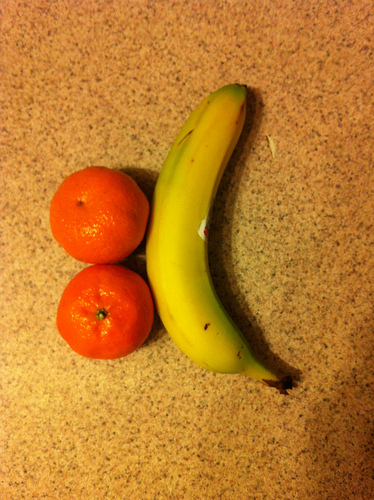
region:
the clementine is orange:
[51, 169, 154, 260]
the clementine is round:
[46, 162, 148, 262]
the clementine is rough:
[52, 266, 155, 360]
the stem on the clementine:
[89, 307, 112, 325]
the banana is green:
[143, 71, 302, 401]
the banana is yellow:
[140, 75, 297, 395]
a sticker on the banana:
[191, 217, 213, 242]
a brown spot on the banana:
[175, 126, 195, 145]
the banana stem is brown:
[245, 361, 290, 397]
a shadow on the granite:
[302, 309, 373, 497]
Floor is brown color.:
[34, 32, 152, 115]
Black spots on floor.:
[34, 380, 191, 459]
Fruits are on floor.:
[26, 177, 260, 389]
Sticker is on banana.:
[188, 205, 214, 252]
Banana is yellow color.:
[167, 178, 210, 310]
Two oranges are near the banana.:
[46, 174, 137, 362]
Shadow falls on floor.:
[67, 179, 291, 377]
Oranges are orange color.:
[42, 171, 153, 342]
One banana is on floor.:
[155, 102, 283, 360]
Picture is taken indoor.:
[18, 64, 334, 482]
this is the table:
[63, 406, 152, 427]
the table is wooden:
[33, 377, 102, 445]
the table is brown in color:
[31, 378, 123, 444]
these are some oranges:
[45, 148, 158, 359]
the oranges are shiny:
[69, 196, 111, 341]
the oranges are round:
[43, 162, 163, 359]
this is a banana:
[149, 61, 300, 390]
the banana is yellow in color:
[195, 144, 215, 167]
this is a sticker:
[195, 219, 209, 233]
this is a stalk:
[251, 367, 293, 392]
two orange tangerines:
[44, 165, 153, 355]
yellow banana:
[146, 83, 290, 391]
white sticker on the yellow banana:
[191, 209, 213, 241]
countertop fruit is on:
[5, 10, 367, 491]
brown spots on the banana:
[186, 97, 257, 360]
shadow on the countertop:
[292, 316, 372, 499]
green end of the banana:
[222, 76, 252, 105]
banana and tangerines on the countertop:
[49, 78, 297, 392]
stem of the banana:
[246, 357, 289, 399]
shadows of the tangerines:
[108, 158, 172, 353]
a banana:
[152, 81, 289, 409]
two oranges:
[49, 169, 155, 361]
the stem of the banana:
[259, 366, 294, 400]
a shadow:
[207, 242, 234, 290]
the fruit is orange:
[45, 170, 157, 360]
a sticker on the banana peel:
[195, 217, 209, 242]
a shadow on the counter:
[299, 384, 372, 494]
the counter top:
[52, 416, 251, 492]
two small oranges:
[48, 168, 165, 363]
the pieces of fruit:
[35, 83, 298, 407]